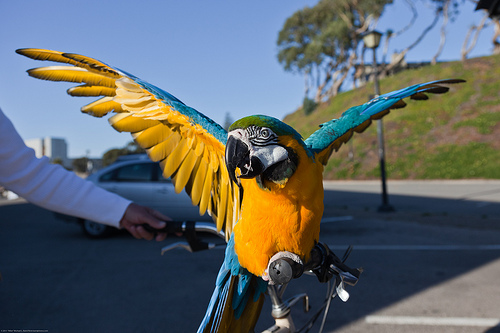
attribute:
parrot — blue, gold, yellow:
[19, 40, 466, 332]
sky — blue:
[96, 1, 276, 62]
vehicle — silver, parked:
[68, 149, 229, 250]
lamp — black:
[357, 23, 397, 215]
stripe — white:
[356, 227, 498, 272]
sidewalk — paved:
[396, 178, 500, 211]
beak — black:
[222, 132, 250, 184]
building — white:
[23, 134, 73, 165]